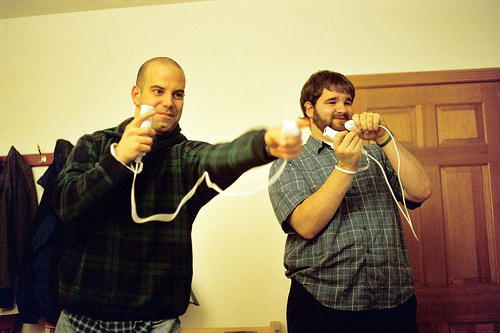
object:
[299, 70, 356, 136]
head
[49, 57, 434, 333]
two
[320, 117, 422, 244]
wii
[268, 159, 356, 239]
arm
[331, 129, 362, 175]
hand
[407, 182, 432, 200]
elbow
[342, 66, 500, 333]
door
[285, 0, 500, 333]
right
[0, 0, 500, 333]
wall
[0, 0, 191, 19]
ceiling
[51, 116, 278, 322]
shirt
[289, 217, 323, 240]
elbow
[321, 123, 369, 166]
controller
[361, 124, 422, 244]
cord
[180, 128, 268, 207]
arm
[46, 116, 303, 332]
body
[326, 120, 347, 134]
jawline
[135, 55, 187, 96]
stubble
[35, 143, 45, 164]
hook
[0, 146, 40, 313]
jacket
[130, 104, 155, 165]
remote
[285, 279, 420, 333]
bottoms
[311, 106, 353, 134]
beard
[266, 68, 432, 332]
guy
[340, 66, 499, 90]
wood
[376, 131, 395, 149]
band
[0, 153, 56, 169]
coat rack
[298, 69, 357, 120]
hair